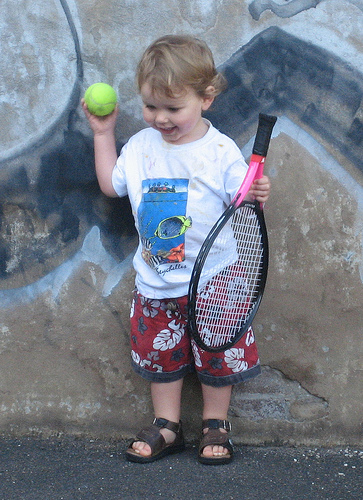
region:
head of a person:
[128, 28, 234, 144]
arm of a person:
[84, 123, 132, 180]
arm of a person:
[234, 167, 269, 206]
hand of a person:
[78, 98, 133, 127]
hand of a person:
[242, 167, 298, 210]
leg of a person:
[145, 338, 202, 422]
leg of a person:
[190, 343, 258, 423]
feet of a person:
[114, 424, 190, 456]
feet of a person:
[187, 427, 249, 463]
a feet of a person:
[105, 421, 189, 469]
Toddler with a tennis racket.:
[60, 32, 281, 463]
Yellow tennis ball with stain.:
[80, 76, 118, 120]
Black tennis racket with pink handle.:
[180, 109, 276, 352]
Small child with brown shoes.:
[75, 33, 272, 465]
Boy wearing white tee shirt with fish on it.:
[76, 32, 286, 470]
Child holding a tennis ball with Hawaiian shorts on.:
[79, 31, 279, 467]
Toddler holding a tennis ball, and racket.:
[69, 29, 283, 474]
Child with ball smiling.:
[76, 28, 273, 461]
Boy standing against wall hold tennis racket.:
[65, 29, 278, 465]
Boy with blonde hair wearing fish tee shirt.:
[74, 29, 280, 468]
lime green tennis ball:
[84, 77, 124, 117]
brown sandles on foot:
[126, 410, 179, 461]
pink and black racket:
[185, 111, 272, 349]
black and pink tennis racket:
[193, 107, 274, 359]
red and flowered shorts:
[121, 288, 263, 381]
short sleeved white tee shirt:
[113, 127, 267, 293]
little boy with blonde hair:
[129, 34, 231, 143]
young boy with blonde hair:
[124, 34, 232, 141]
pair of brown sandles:
[124, 410, 244, 464]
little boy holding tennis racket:
[128, 26, 292, 357]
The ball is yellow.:
[81, 77, 119, 118]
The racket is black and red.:
[183, 105, 279, 358]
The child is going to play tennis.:
[82, 30, 274, 466]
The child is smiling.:
[78, 26, 284, 463]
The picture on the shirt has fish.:
[134, 174, 188, 275]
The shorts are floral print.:
[124, 258, 262, 386]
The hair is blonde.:
[131, 33, 226, 102]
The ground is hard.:
[0, 435, 359, 497]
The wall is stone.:
[0, 0, 362, 449]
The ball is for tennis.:
[79, 78, 118, 118]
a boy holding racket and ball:
[77, 31, 274, 469]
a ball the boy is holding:
[77, 79, 119, 118]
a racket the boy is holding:
[179, 107, 278, 356]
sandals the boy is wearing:
[121, 411, 247, 468]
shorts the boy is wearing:
[125, 261, 267, 389]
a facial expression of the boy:
[139, 94, 201, 144]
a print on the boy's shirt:
[146, 211, 191, 241]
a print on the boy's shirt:
[135, 174, 195, 278]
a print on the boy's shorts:
[167, 345, 187, 364]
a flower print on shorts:
[206, 353, 224, 372]